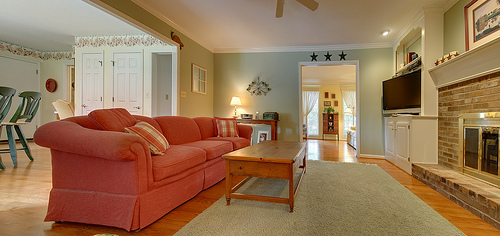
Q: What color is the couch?
A: Orange.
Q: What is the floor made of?
A: Wood.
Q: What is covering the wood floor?
A: Rug.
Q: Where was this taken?
A: Living room.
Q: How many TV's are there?
A: 1.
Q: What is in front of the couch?
A: Coffee table.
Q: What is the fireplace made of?
A: Bricks.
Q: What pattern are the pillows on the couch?
A: Plaid.